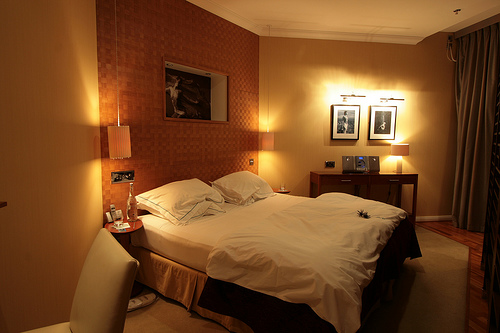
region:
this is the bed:
[204, 195, 359, 305]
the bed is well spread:
[227, 200, 378, 312]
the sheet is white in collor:
[273, 211, 345, 270]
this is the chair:
[63, 241, 131, 323]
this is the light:
[390, 138, 410, 171]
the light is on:
[383, 134, 410, 174]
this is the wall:
[5, 64, 83, 195]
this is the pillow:
[157, 177, 217, 227]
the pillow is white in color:
[154, 177, 206, 219]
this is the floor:
[420, 245, 463, 316]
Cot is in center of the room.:
[150, 166, 362, 287]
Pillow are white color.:
[129, 168, 283, 227]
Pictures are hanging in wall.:
[311, 90, 403, 144]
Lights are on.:
[92, 88, 436, 314]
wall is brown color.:
[41, 58, 392, 159]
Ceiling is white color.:
[253, 8, 420, 43]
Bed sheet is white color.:
[181, 180, 343, 290]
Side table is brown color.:
[101, 200, 146, 267]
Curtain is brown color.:
[441, 46, 498, 209]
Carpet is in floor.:
[423, 220, 482, 311]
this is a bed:
[209, 167, 368, 325]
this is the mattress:
[177, 222, 213, 261]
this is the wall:
[13, 30, 65, 239]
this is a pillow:
[178, 178, 200, 205]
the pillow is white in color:
[172, 178, 194, 208]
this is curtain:
[458, 35, 478, 187]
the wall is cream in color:
[39, 37, 74, 107]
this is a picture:
[364, 107, 396, 141]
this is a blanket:
[243, 193, 320, 273]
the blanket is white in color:
[298, 220, 329, 258]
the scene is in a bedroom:
[21, 8, 473, 330]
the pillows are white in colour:
[138, 174, 227, 222]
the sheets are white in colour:
[195, 183, 392, 330]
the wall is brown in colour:
[269, 28, 316, 130]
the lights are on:
[280, 83, 483, 248]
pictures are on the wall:
[278, 71, 411, 147]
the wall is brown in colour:
[117, 19, 262, 194]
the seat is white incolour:
[56, 233, 151, 318]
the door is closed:
[2, 3, 94, 255]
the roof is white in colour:
[316, 0, 439, 24]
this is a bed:
[189, 194, 387, 301]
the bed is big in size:
[193, 188, 385, 323]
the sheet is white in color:
[250, 193, 346, 268]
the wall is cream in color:
[4, 108, 96, 196]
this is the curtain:
[455, 65, 494, 127]